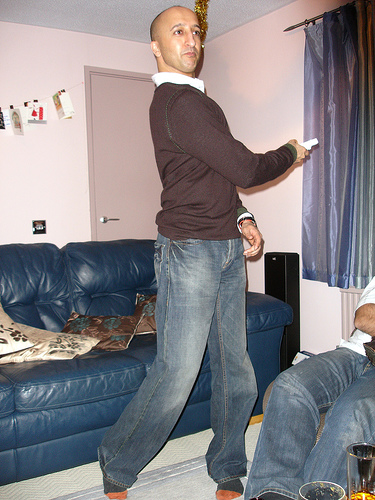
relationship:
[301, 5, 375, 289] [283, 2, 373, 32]
curtain on rod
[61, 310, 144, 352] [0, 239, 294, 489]
pillow on couch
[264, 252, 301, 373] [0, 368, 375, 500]
speaker on floor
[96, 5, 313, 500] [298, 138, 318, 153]
man has remote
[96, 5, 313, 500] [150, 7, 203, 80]
man has head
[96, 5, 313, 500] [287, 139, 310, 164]
man has hand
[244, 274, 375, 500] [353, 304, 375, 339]
man has elbow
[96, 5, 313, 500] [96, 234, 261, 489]
man has jean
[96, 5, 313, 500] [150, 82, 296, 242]
man has shirt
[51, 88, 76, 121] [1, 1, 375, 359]
card on wall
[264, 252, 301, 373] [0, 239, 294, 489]
speaker behind couch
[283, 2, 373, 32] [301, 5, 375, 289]
rod above curtain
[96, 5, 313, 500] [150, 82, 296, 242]
man wearing shirt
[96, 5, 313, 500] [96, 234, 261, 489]
man wearing jean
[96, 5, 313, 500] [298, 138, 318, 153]
man holding remote